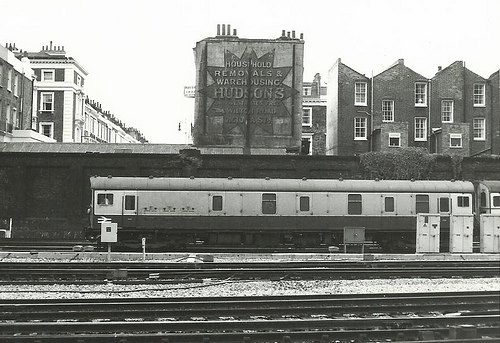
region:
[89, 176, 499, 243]
A train on a rail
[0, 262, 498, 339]
Train rails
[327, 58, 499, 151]
Housing complex in the background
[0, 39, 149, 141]
A building in the background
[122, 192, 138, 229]
A door with a window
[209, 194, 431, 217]
Windows on a train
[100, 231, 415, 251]
Wheels on a train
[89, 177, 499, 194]
Roof of a train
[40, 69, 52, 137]
Windows on a building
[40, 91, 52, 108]
A rectangle window on a building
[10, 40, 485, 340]
a black and white photo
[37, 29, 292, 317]
this picture is in black and white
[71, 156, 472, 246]
an old passenger train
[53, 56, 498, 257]
the train is going through the city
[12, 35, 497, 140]
buildings in the background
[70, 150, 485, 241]
this is a two toned train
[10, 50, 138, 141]
an edifice in the area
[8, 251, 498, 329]
train tracks on the ground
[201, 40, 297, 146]
a factory above the train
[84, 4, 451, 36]
a cloudy sky above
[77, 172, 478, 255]
parked passenger car of a train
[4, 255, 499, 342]
rusty metal train tracks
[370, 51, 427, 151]
multi story brick building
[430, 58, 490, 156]
multi story brick building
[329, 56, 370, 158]
multi story brick building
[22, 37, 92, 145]
multi story brick building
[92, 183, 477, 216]
row of round edged windows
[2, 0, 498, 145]
crisp white sky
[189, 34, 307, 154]
large faded bill board type advertisement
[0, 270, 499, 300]
light gray gravel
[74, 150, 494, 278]
This is a train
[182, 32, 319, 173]
This is an advertisement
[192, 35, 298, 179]
Advertisement on side of building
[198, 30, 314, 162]
Advertisement is worn out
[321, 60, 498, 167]
These are townhomes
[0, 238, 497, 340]
Numerous train tracks in a row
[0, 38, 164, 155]
Building in the background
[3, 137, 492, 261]
Large wall next to train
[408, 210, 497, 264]
There are three power boxes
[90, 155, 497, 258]
Two train cars on track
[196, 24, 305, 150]
old building by train tracks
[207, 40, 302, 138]
sign on side of building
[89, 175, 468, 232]
long white train on tracks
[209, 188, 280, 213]
windows on side of train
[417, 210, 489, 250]
white boxes by train tracks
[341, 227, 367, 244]
small metal item by tracks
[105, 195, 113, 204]
side window of conductors box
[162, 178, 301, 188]
black roof on top of train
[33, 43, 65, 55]
chimneys on top of building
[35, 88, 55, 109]
window on side of building